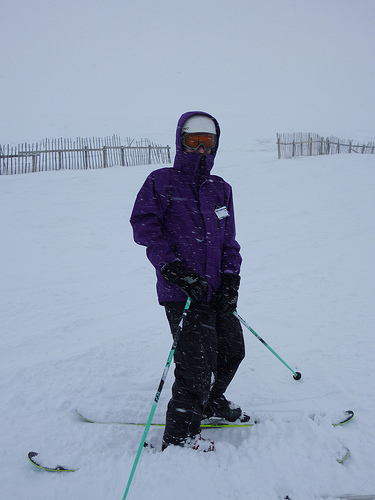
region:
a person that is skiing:
[104, 92, 334, 337]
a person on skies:
[47, 110, 367, 455]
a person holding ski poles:
[139, 249, 361, 492]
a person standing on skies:
[56, 294, 374, 493]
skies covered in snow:
[60, 348, 337, 499]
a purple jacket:
[108, 118, 291, 357]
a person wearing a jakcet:
[102, 148, 291, 341]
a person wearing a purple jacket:
[114, 158, 322, 311]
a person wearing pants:
[102, 174, 297, 412]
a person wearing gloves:
[123, 166, 337, 399]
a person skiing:
[89, 106, 311, 465]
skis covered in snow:
[37, 395, 371, 489]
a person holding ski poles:
[103, 84, 344, 456]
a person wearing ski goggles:
[136, 88, 260, 172]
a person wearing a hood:
[152, 100, 240, 190]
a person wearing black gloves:
[109, 106, 285, 348]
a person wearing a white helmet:
[104, 95, 253, 255]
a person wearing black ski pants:
[124, 94, 297, 468]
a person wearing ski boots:
[126, 74, 254, 479]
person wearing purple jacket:
[105, 107, 305, 457]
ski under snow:
[47, 390, 362, 468]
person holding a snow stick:
[108, 272, 209, 498]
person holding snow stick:
[208, 280, 318, 384]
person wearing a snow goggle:
[94, 96, 261, 462]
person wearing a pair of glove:
[86, 87, 280, 466]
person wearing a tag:
[119, 109, 260, 460]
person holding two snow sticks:
[84, 255, 314, 498]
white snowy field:
[22, 183, 110, 255]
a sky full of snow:
[69, 26, 273, 94]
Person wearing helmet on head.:
[178, 116, 226, 139]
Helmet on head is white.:
[180, 107, 235, 151]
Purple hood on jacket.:
[168, 106, 247, 174]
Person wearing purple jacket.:
[113, 194, 219, 256]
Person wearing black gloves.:
[178, 273, 247, 307]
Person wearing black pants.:
[173, 325, 241, 392]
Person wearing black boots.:
[162, 385, 252, 448]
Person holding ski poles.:
[165, 270, 254, 327]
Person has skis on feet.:
[139, 362, 259, 483]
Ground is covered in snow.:
[39, 318, 251, 459]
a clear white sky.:
[48, 40, 113, 63]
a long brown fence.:
[270, 127, 374, 157]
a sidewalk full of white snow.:
[292, 187, 337, 272]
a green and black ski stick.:
[225, 307, 304, 379]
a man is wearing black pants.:
[182, 339, 205, 397]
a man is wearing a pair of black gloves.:
[156, 255, 211, 305]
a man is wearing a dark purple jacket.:
[184, 206, 211, 261]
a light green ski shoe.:
[21, 445, 92, 476]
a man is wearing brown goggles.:
[181, 130, 220, 153]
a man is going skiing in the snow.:
[14, 91, 373, 498]